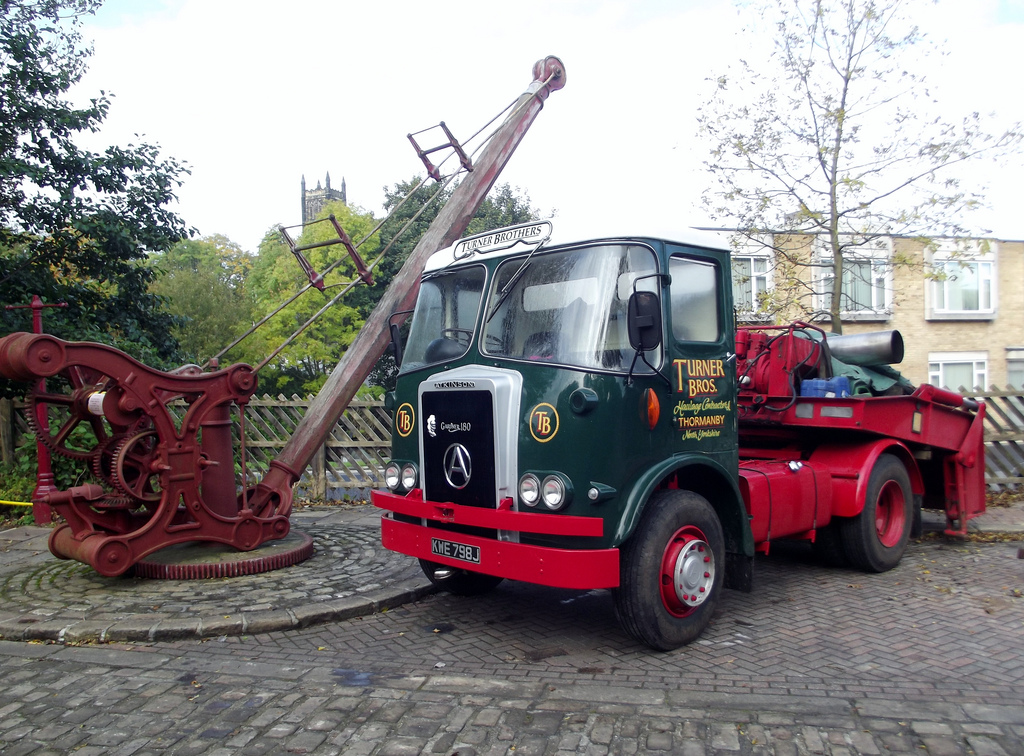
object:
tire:
[611, 488, 724, 651]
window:
[811, 232, 894, 321]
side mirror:
[627, 273, 673, 394]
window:
[669, 252, 727, 342]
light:
[540, 475, 565, 511]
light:
[518, 473, 541, 507]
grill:
[422, 390, 499, 540]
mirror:
[627, 291, 662, 351]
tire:
[844, 452, 915, 572]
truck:
[369, 221, 987, 653]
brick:
[794, 631, 824, 641]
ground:
[0, 508, 1024, 756]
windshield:
[399, 244, 662, 375]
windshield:
[399, 265, 486, 375]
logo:
[443, 442, 471, 490]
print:
[673, 359, 727, 399]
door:
[663, 241, 737, 488]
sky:
[0, 0, 1024, 254]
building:
[685, 224, 1024, 493]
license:
[431, 537, 480, 564]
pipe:
[826, 330, 905, 367]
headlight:
[384, 459, 419, 492]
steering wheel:
[440, 328, 509, 354]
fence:
[169, 381, 1021, 512]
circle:
[395, 402, 415, 437]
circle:
[529, 402, 559, 443]